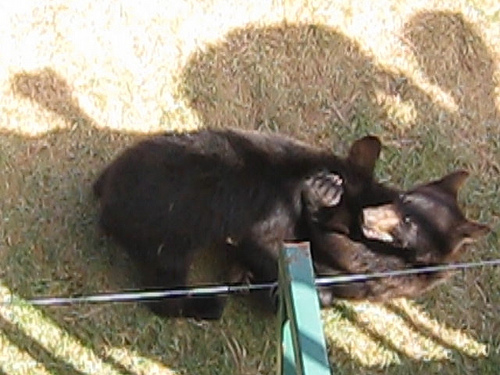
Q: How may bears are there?
A: 2.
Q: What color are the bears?
A: Black.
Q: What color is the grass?
A: Green.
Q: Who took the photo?
A: Bystander.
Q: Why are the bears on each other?
A: Playing.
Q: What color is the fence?
A: Grey.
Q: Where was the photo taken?
A: In the grass.